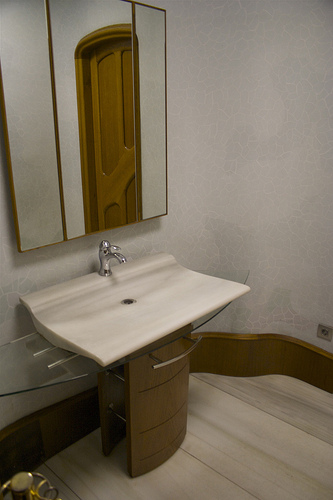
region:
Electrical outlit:
[314, 321, 332, 344]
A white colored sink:
[65, 301, 116, 345]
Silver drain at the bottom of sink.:
[121, 297, 140, 306]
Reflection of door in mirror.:
[68, 16, 158, 228]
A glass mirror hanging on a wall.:
[15, 95, 51, 157]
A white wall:
[247, 101, 305, 217]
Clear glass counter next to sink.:
[10, 351, 32, 383]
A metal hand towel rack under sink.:
[153, 353, 169, 372]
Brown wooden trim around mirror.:
[163, 9, 169, 216]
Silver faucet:
[94, 238, 125, 279]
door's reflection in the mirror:
[65, 30, 161, 235]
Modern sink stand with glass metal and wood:
[21, 324, 244, 487]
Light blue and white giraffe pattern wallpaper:
[225, 140, 324, 328]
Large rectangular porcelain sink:
[6, 237, 252, 362]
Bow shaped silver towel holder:
[142, 329, 203, 373]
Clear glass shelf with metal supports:
[1, 303, 86, 395]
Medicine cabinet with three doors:
[3, 2, 186, 253]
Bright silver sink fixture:
[72, 230, 136, 273]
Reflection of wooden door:
[67, 23, 157, 250]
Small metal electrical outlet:
[297, 311, 330, 358]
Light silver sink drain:
[97, 284, 145, 313]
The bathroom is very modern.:
[7, 88, 330, 480]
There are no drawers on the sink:
[121, 353, 204, 473]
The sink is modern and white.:
[25, 249, 249, 359]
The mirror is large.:
[0, 3, 174, 217]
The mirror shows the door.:
[16, 44, 175, 215]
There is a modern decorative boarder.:
[188, 331, 330, 387]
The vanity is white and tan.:
[18, 238, 240, 482]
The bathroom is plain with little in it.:
[16, 22, 321, 440]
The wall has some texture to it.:
[174, 18, 305, 294]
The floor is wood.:
[193, 379, 322, 497]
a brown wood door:
[67, 20, 151, 234]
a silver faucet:
[96, 238, 128, 276]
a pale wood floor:
[5, 370, 331, 497]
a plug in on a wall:
[314, 323, 331, 340]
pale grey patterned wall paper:
[2, 2, 330, 428]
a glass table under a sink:
[0, 262, 252, 397]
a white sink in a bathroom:
[14, 249, 249, 368]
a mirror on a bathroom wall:
[1, 0, 168, 251]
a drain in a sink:
[121, 297, 136, 304]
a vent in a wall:
[0, 415, 49, 483]